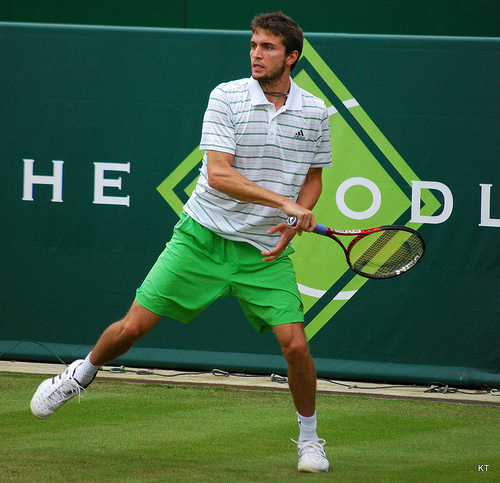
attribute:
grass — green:
[0, 368, 499, 479]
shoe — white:
[26, 360, 92, 418]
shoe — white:
[290, 435, 330, 475]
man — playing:
[28, 13, 331, 473]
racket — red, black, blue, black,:
[285, 217, 426, 283]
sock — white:
[73, 353, 98, 386]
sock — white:
[293, 410, 320, 443]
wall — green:
[0, 19, 499, 399]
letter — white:
[21, 156, 67, 205]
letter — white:
[92, 162, 130, 209]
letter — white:
[333, 178, 380, 222]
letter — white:
[409, 178, 455, 230]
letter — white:
[475, 182, 497, 232]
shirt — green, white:
[184, 78, 327, 255]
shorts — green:
[137, 208, 307, 337]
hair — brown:
[249, 9, 306, 62]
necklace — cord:
[261, 89, 287, 99]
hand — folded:
[281, 200, 315, 235]